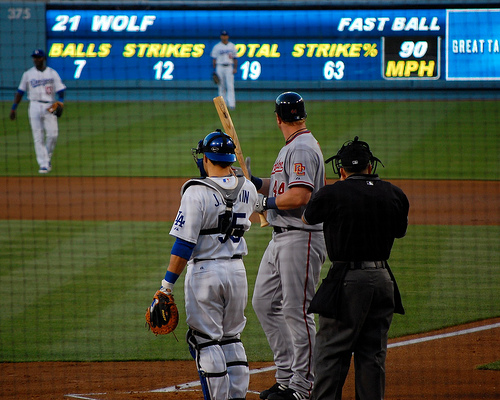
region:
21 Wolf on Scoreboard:
[52, 14, 160, 35]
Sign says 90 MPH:
[382, 39, 439, 76]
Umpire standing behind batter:
[304, 137, 410, 397]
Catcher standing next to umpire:
[142, 130, 259, 397]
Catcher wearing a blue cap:
[193, 131, 239, 166]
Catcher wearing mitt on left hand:
[145, 283, 180, 338]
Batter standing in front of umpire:
[255, 87, 325, 399]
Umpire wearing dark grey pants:
[309, 259, 396, 399]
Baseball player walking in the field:
[4, 46, 71, 174]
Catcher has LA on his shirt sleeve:
[171, 206, 188, 233]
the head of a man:
[186, 135, 250, 185]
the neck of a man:
[194, 139, 243, 184]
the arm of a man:
[136, 210, 228, 342]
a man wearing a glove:
[129, 172, 282, 372]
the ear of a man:
[271, 97, 298, 132]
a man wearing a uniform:
[119, 129, 279, 357]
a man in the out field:
[29, 37, 146, 182]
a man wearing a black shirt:
[281, 127, 433, 309]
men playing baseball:
[121, 79, 413, 339]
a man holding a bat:
[189, 50, 364, 235]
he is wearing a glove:
[143, 285, 184, 333]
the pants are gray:
[282, 247, 302, 285]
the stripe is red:
[301, 244, 313, 271]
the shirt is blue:
[176, 241, 188, 253]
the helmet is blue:
[201, 132, 234, 159]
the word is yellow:
[296, 41, 363, 61]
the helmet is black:
[275, 90, 307, 115]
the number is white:
[396, 38, 431, 59]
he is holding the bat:
[230, 157, 276, 216]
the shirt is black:
[346, 196, 373, 227]